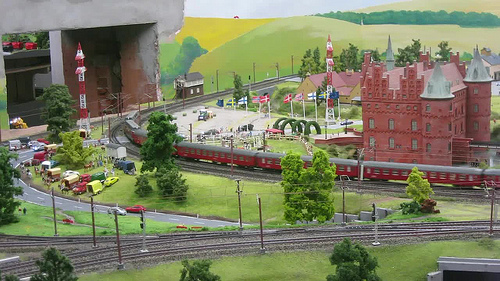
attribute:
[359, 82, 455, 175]
building — brick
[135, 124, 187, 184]
trees — leafy, green, pictured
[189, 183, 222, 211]
grass — green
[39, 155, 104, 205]
vehicles — parked, different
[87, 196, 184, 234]
cars — paired, parked, red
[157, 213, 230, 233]
street — grey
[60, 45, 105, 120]
tower — red, white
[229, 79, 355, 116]
flags — different, ten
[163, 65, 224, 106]
house — brown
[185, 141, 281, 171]
train — red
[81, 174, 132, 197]
car — bright, red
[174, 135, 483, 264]
railroads — converging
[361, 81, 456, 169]
station — two-story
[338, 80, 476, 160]
buliding — red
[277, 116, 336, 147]
hedges — arched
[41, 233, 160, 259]
tracks — pictured, railroad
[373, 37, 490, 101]
towers — gray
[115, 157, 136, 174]
wagon — gray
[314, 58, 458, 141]
castle — red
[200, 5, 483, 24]
mountains — distant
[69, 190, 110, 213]
tires — rubber